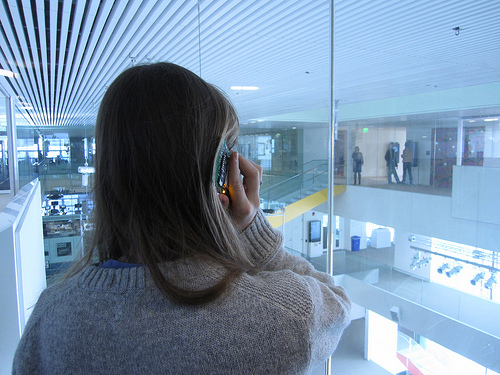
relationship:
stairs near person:
[262, 165, 350, 236] [10, 59, 353, 374]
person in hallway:
[10, 59, 353, 374] [2, 2, 460, 371]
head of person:
[82, 62, 254, 269] [10, 59, 353, 374]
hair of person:
[91, 60, 238, 250] [10, 59, 353, 374]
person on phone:
[10, 59, 353, 374] [215, 130, 251, 200]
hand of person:
[212, 147, 269, 234] [10, 59, 353, 374]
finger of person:
[224, 146, 249, 211] [10, 59, 353, 374]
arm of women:
[221, 157, 351, 337] [15, 53, 360, 373]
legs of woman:
[351, 170, 363, 185] [347, 142, 365, 186]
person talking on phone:
[10, 62, 348, 373] [211, 137, 240, 193]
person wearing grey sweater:
[10, 62, 348, 373] [10, 211, 350, 374]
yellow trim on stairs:
[254, 182, 348, 230] [258, 164, 348, 231]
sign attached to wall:
[307, 220, 324, 242] [286, 211, 328, 261]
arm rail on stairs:
[276, 172, 331, 200] [267, 157, 332, 202]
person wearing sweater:
[10, 59, 353, 374] [11, 206, 351, 372]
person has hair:
[10, 59, 353, 374] [22, 60, 262, 315]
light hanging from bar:
[408, 249, 431, 274] [405, 239, 498, 274]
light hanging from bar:
[434, 263, 456, 280] [405, 239, 498, 274]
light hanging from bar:
[472, 267, 492, 295] [405, 239, 498, 274]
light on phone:
[214, 184, 229, 196] [204, 139, 261, 198]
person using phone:
[10, 59, 353, 374] [188, 147, 267, 197]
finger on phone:
[226, 150, 249, 212] [214, 142, 231, 194]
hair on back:
[22, 60, 262, 315] [30, 251, 314, 371]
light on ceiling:
[228, 77, 268, 98] [268, 20, 420, 123]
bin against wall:
[348, 231, 363, 250] [348, 216, 368, 251]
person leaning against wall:
[382, 140, 399, 182] [355, 128, 382, 159]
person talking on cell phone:
[10, 59, 353, 374] [213, 138, 231, 197]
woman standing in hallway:
[347, 139, 364, 184] [251, 155, 458, 204]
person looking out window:
[10, 59, 353, 374] [334, 114, 496, 232]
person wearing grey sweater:
[10, 59, 353, 374] [57, 278, 306, 370]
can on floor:
[345, 234, 370, 253] [335, 247, 380, 263]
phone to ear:
[211, 137, 240, 193] [211, 147, 239, 192]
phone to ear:
[211, 141, 246, 193] [215, 150, 236, 181]